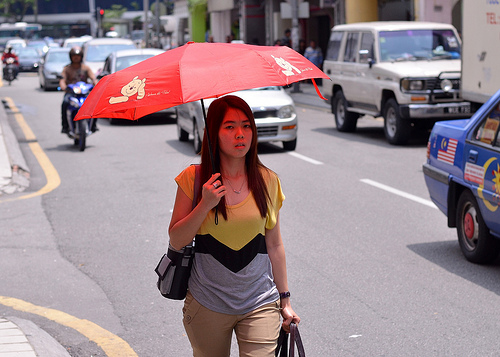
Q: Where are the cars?
A: On road.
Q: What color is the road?
A: Gray.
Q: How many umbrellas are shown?
A: One.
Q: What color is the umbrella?
A: Red.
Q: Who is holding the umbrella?
A: Woman.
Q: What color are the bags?
A: Black.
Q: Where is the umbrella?
A: Woman's hand.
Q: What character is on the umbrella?
A: Winnie the Pooh.